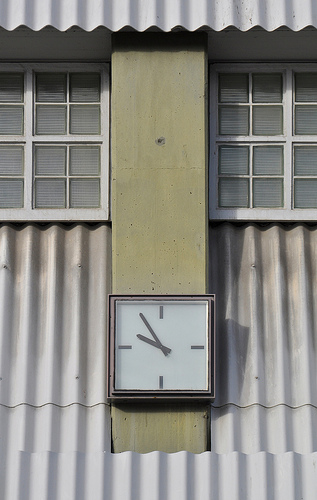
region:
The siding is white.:
[5, 230, 105, 496]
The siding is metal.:
[4, 241, 106, 477]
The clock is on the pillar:
[109, 295, 219, 449]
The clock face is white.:
[111, 294, 212, 409]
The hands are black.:
[124, 309, 172, 355]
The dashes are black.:
[113, 298, 206, 394]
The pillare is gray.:
[112, 240, 216, 442]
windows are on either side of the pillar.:
[8, 64, 312, 207]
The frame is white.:
[209, 62, 316, 218]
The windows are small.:
[210, 64, 315, 207]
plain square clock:
[105, 292, 217, 399]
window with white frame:
[208, 59, 315, 220]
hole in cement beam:
[153, 135, 166, 146]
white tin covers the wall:
[1, 222, 110, 481]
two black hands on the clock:
[136, 311, 171, 357]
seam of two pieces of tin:
[1, 396, 109, 410]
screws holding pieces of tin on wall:
[76, 261, 82, 268]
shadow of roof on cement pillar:
[108, 29, 209, 55]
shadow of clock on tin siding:
[217, 311, 251, 410]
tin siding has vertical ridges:
[3, 230, 100, 498]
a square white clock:
[98, 284, 237, 415]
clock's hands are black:
[127, 302, 175, 365]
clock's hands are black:
[118, 302, 186, 391]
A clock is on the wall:
[94, 286, 219, 410]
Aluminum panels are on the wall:
[218, 228, 312, 492]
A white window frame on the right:
[201, 53, 313, 229]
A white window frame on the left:
[8, 48, 123, 231]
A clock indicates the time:
[103, 288, 219, 405]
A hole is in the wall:
[148, 127, 172, 157]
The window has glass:
[214, 62, 289, 147]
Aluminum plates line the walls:
[218, 231, 309, 457]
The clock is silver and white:
[98, 280, 218, 412]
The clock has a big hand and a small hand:
[125, 304, 173, 360]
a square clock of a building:
[105, 290, 216, 402]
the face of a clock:
[116, 302, 207, 390]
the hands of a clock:
[137, 310, 173, 357]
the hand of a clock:
[134, 332, 175, 354]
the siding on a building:
[240, 279, 308, 445]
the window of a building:
[210, 69, 291, 214]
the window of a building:
[289, 70, 314, 215]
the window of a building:
[27, 68, 103, 219]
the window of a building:
[2, 66, 27, 217]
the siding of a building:
[6, 274, 87, 423]